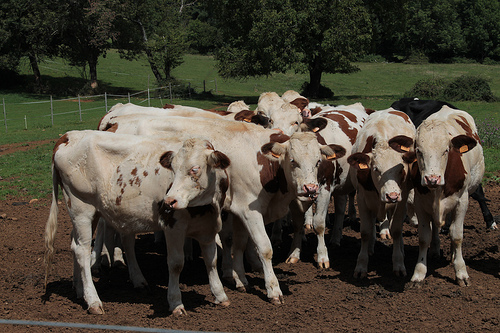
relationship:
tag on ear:
[458, 143, 469, 155] [453, 134, 478, 154]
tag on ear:
[401, 143, 411, 152] [388, 133, 418, 154]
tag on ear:
[359, 163, 371, 170] [347, 153, 371, 171]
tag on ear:
[325, 151, 337, 160] [319, 145, 347, 163]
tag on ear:
[312, 125, 321, 134] [302, 116, 327, 132]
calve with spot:
[40, 130, 231, 319] [130, 167, 140, 177]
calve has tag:
[385, 102, 487, 290] [458, 143, 469, 155]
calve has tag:
[385, 102, 487, 290] [401, 143, 411, 152]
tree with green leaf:
[253, 0, 371, 100] [331, 30, 338, 37]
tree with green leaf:
[253, 0, 371, 100] [329, 58, 341, 66]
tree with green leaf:
[253, 0, 371, 100] [295, 56, 304, 63]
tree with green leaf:
[253, 0, 371, 100] [269, 33, 278, 46]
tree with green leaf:
[253, 0, 371, 100] [306, 16, 315, 26]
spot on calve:
[130, 167, 140, 177] [40, 130, 231, 319]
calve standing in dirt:
[40, 130, 231, 319] [0, 182, 499, 333]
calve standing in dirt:
[102, 110, 347, 306] [0, 182, 499, 333]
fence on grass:
[0, 78, 217, 138] [0, 42, 500, 200]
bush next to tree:
[319, 84, 334, 97] [253, 0, 371, 100]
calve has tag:
[345, 107, 417, 280] [401, 143, 411, 152]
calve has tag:
[345, 107, 417, 280] [359, 163, 371, 170]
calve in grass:
[40, 130, 231, 319] [0, 42, 500, 200]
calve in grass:
[102, 110, 347, 306] [0, 42, 500, 200]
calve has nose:
[40, 130, 231, 319] [163, 195, 177, 210]